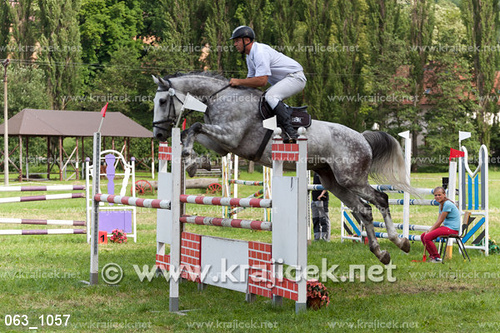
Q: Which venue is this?
A: This is a lawn.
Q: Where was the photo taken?
A: It was taken at the lawn.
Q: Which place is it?
A: It is a lawn.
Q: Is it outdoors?
A: Yes, it is outdoors.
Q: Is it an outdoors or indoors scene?
A: It is outdoors.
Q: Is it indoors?
A: No, it is outdoors.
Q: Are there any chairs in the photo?
A: Yes, there is a chair.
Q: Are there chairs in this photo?
A: Yes, there is a chair.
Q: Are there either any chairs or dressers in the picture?
A: Yes, there is a chair.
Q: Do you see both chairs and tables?
A: No, there is a chair but no tables.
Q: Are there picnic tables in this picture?
A: No, there are no picnic tables.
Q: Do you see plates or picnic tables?
A: No, there are no picnic tables or plates.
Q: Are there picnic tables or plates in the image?
A: No, there are no picnic tables or plates.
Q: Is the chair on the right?
A: Yes, the chair is on the right of the image.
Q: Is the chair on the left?
A: No, the chair is on the right of the image.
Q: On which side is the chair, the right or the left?
A: The chair is on the right of the image.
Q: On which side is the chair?
A: The chair is on the right of the image.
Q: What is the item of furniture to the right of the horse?
A: The piece of furniture is a chair.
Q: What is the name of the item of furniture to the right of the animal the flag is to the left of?
A: The piece of furniture is a chair.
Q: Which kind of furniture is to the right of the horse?
A: The piece of furniture is a chair.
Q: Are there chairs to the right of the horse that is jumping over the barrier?
A: Yes, there is a chair to the right of the horse.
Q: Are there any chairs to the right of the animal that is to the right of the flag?
A: Yes, there is a chair to the right of the horse.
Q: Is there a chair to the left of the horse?
A: No, the chair is to the right of the horse.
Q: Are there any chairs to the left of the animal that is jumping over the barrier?
A: No, the chair is to the right of the horse.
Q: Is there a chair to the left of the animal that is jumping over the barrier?
A: No, the chair is to the right of the horse.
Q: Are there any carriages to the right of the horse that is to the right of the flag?
A: No, there is a chair to the right of the horse.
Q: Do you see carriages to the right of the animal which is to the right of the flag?
A: No, there is a chair to the right of the horse.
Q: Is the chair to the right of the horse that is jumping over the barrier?
A: Yes, the chair is to the right of the horse.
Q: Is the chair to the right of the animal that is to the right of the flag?
A: Yes, the chair is to the right of the horse.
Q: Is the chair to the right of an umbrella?
A: No, the chair is to the right of the horse.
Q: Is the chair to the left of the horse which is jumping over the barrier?
A: No, the chair is to the right of the horse.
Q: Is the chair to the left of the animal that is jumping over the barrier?
A: No, the chair is to the right of the horse.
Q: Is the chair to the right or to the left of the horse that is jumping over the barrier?
A: The chair is to the right of the horse.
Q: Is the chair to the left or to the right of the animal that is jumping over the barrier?
A: The chair is to the right of the horse.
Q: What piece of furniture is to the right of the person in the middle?
A: The piece of furniture is a chair.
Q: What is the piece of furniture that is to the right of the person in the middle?
A: The piece of furniture is a chair.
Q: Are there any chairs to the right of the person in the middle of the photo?
A: Yes, there is a chair to the right of the person.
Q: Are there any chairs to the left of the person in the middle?
A: No, the chair is to the right of the person.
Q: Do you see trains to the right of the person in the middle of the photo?
A: No, there is a chair to the right of the person.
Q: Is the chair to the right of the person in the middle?
A: Yes, the chair is to the right of the person.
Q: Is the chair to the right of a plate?
A: No, the chair is to the right of the person.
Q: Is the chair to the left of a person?
A: No, the chair is to the right of a person.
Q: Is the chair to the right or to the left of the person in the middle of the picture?
A: The chair is to the right of the person.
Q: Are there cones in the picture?
A: No, there are no cones.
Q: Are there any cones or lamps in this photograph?
A: No, there are no cones or lamps.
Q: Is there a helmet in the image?
A: Yes, there is a helmet.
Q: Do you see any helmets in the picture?
A: Yes, there is a helmet.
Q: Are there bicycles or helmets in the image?
A: Yes, there is a helmet.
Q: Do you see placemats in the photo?
A: No, there are no placemats.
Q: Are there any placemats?
A: No, there are no placemats.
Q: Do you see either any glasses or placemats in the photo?
A: No, there are no placemats or glasses.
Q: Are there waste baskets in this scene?
A: No, there are no waste baskets.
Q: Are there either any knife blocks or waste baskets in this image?
A: No, there are no waste baskets or knife blocks.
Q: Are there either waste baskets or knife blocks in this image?
A: No, there are no waste baskets or knife blocks.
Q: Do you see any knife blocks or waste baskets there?
A: No, there are no waste baskets or knife blocks.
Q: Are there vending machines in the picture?
A: No, there are no vending machines.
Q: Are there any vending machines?
A: No, there are no vending machines.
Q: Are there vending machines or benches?
A: No, there are no vending machines or benches.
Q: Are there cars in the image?
A: No, there are no cars.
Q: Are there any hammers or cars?
A: No, there are no cars or hammers.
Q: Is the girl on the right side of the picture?
A: Yes, the girl is on the right of the image.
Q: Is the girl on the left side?
A: No, the girl is on the right of the image.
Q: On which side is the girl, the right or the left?
A: The girl is on the right of the image.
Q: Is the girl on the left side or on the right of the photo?
A: The girl is on the right of the image.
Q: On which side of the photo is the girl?
A: The girl is on the right of the image.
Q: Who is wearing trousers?
A: The girl is wearing trousers.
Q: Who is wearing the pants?
A: The girl is wearing trousers.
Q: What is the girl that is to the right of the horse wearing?
A: The girl is wearing trousers.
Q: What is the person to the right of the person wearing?
A: The girl is wearing trousers.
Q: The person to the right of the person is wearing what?
A: The girl is wearing trousers.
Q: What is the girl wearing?
A: The girl is wearing trousers.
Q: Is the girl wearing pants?
A: Yes, the girl is wearing pants.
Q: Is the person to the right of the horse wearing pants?
A: Yes, the girl is wearing pants.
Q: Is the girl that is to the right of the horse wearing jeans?
A: No, the girl is wearing pants.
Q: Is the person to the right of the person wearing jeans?
A: No, the girl is wearing pants.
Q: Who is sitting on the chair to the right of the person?
A: The girl is sitting on the chair.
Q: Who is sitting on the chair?
A: The girl is sitting on the chair.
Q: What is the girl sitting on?
A: The girl is sitting on the chair.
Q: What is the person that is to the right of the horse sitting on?
A: The girl is sitting on the chair.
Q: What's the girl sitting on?
A: The girl is sitting on the chair.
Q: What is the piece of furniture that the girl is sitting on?
A: The piece of furniture is a chair.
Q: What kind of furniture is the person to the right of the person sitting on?
A: The girl is sitting on the chair.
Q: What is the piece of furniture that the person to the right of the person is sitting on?
A: The piece of furniture is a chair.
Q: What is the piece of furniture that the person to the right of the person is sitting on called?
A: The piece of furniture is a chair.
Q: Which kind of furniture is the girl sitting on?
A: The girl is sitting on the chair.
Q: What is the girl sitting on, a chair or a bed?
A: The girl is sitting on a chair.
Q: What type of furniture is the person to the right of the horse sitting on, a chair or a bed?
A: The girl is sitting on a chair.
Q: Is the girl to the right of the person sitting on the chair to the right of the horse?
A: Yes, the girl is sitting on the chair.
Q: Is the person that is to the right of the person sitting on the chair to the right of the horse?
A: Yes, the girl is sitting on the chair.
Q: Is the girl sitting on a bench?
A: No, the girl is sitting on the chair.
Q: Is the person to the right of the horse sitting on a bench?
A: No, the girl is sitting on the chair.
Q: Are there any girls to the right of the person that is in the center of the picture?
A: Yes, there is a girl to the right of the person.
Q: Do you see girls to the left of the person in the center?
A: No, the girl is to the right of the person.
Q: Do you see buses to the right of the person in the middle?
A: No, there is a girl to the right of the person.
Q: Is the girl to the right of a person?
A: Yes, the girl is to the right of a person.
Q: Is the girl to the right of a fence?
A: No, the girl is to the right of a person.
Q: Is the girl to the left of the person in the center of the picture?
A: No, the girl is to the right of the person.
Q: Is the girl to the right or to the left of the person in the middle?
A: The girl is to the right of the person.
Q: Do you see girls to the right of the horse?
A: Yes, there is a girl to the right of the horse.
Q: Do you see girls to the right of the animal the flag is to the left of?
A: Yes, there is a girl to the right of the horse.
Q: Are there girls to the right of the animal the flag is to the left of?
A: Yes, there is a girl to the right of the horse.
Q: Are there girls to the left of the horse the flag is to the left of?
A: No, the girl is to the right of the horse.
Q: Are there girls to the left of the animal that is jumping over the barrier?
A: No, the girl is to the right of the horse.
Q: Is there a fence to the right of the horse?
A: No, there is a girl to the right of the horse.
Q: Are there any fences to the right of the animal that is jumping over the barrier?
A: No, there is a girl to the right of the horse.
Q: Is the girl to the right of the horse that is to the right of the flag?
A: Yes, the girl is to the right of the horse.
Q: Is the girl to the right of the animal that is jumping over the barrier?
A: Yes, the girl is to the right of the horse.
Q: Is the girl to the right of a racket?
A: No, the girl is to the right of the horse.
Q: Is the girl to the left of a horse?
A: No, the girl is to the right of a horse.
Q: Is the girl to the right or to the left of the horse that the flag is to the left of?
A: The girl is to the right of the horse.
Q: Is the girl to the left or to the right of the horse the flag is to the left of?
A: The girl is to the right of the horse.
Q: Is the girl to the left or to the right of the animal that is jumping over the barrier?
A: The girl is to the right of the horse.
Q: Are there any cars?
A: No, there are no cars.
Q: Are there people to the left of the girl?
A: Yes, there is a person to the left of the girl.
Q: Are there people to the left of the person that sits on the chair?
A: Yes, there is a person to the left of the girl.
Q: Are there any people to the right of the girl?
A: No, the person is to the left of the girl.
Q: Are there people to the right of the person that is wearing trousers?
A: No, the person is to the left of the girl.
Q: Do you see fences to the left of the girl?
A: No, there is a person to the left of the girl.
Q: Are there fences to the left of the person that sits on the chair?
A: No, there is a person to the left of the girl.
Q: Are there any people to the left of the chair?
A: Yes, there is a person to the left of the chair.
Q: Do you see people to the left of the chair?
A: Yes, there is a person to the left of the chair.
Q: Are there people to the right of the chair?
A: No, the person is to the left of the chair.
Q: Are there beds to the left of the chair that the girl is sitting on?
A: No, there is a person to the left of the chair.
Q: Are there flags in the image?
A: Yes, there is a flag.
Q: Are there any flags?
A: Yes, there is a flag.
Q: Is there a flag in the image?
A: Yes, there is a flag.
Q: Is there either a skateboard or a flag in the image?
A: Yes, there is a flag.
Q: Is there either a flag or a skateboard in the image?
A: Yes, there is a flag.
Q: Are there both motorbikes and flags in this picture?
A: No, there is a flag but no motorcycles.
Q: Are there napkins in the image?
A: No, there are no napkins.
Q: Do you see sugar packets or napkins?
A: No, there are no napkins or sugar packets.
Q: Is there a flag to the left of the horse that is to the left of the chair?
A: Yes, there is a flag to the left of the horse.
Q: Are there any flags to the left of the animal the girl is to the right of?
A: Yes, there is a flag to the left of the horse.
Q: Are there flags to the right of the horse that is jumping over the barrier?
A: No, the flag is to the left of the horse.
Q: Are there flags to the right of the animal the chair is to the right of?
A: No, the flag is to the left of the horse.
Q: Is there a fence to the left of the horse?
A: No, there is a flag to the left of the horse.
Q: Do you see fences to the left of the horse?
A: No, there is a flag to the left of the horse.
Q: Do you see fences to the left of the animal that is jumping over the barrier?
A: No, there is a flag to the left of the horse.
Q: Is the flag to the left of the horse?
A: Yes, the flag is to the left of the horse.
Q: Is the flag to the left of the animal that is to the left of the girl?
A: Yes, the flag is to the left of the horse.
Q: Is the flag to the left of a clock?
A: No, the flag is to the left of the horse.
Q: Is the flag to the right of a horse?
A: No, the flag is to the left of a horse.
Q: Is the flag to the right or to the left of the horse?
A: The flag is to the left of the horse.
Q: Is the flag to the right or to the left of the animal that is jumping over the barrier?
A: The flag is to the left of the horse.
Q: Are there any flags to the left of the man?
A: Yes, there is a flag to the left of the man.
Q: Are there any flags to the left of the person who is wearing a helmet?
A: Yes, there is a flag to the left of the man.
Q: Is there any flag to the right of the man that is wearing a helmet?
A: No, the flag is to the left of the man.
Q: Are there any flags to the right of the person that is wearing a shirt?
A: No, the flag is to the left of the man.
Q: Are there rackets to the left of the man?
A: No, there is a flag to the left of the man.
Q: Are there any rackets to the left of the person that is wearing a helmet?
A: No, there is a flag to the left of the man.